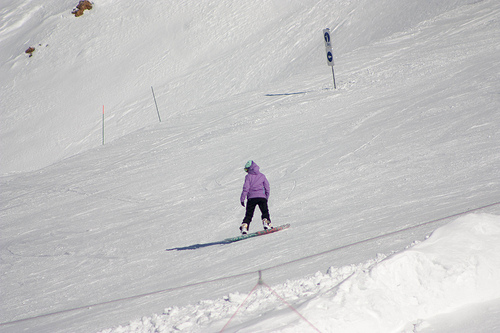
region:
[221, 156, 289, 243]
person on a snowboard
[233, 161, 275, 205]
fluffy purple jacket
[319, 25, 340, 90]
sign in the snow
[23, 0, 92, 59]
rocks sticking out of snow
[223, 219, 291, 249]
multi colored snowboard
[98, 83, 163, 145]
poles in the snow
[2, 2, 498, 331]
white snow on the ground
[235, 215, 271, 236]
white and black boots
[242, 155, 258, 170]
boarder with light blue hat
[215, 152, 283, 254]
person snowboarding downhill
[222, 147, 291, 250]
a little girl on a snowboard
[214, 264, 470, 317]
piles of white snow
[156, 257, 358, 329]
the shadow from a zip line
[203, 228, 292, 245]
a snowboard on the ground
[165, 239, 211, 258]
a little girl's shadow on the snow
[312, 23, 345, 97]
a black and white sign on a pole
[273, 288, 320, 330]
a red string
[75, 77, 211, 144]
two poles in the snow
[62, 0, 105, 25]
a brown rock protruding from the snow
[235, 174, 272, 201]
a purple coat on a little girl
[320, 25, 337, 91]
sign for directions for skiers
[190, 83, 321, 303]
person going down hill on snowboard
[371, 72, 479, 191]
smooth down hill snow for skiiers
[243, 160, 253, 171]
green hat on the snowboarder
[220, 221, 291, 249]
snow board in use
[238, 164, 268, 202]
purple hoodie jacket worn by skier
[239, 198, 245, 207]
left glove worn by skier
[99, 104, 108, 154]
measurement pole in the snow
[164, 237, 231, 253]
shadow of the snow boarder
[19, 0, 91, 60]
small mountain rocks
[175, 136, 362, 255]
a snowboard on the snow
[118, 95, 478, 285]
a snowboarder on a hill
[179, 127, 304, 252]
a snow boarder wearing a purple jacket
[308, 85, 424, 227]
snow on the ground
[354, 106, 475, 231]
white snow on the ground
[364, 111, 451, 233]
ground cover in snow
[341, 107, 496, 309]
ground covered in white snow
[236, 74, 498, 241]
hill covered in snow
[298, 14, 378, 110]
sign in the snow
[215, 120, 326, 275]
a person snowingboard on snow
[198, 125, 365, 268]
a person skiing on snow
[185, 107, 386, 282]
person skiing on hill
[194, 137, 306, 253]
peson snowboarding in the snow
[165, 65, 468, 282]
a person snowboarding down hill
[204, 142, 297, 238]
a person with a purple jacket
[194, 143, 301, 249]
a snowboarder with purple jacket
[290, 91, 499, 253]
white snow covering the ground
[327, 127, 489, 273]
snow covering the ground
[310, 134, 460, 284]
ground covered in snow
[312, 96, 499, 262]
snow cover in white snow